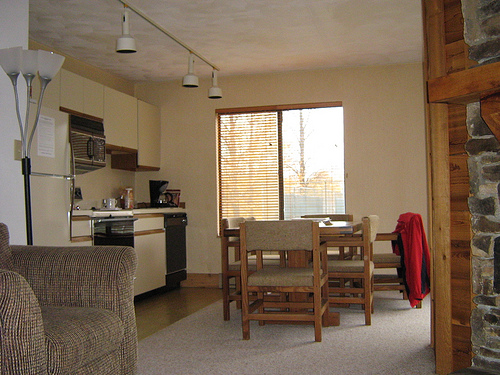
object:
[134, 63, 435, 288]
wall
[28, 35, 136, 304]
wall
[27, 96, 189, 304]
kitchenette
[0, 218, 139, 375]
chair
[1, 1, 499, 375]
room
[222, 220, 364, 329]
table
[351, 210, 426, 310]
chair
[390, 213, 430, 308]
jacket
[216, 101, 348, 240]
window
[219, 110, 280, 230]
blinds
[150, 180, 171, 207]
pot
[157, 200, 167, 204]
coffee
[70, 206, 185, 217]
counter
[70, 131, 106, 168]
microwave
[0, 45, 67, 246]
lamp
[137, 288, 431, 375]
carpet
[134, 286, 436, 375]
floor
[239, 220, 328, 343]
chair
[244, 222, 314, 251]
back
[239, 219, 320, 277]
top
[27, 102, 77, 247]
fridge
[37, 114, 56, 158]
paper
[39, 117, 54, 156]
lettering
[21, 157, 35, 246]
pole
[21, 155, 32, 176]
top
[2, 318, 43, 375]
pattern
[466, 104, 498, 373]
place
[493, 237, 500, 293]
fire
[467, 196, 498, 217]
brick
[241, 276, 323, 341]
bottom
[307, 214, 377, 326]
chairs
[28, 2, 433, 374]
kitchen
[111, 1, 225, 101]
style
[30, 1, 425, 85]
ceiling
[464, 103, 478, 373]
edge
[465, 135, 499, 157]
stone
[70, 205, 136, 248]
stove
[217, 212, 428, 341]
set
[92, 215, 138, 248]
oven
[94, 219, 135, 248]
door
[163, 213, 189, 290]
dishwasher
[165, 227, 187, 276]
metal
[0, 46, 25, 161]
head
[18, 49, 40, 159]
head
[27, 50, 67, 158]
head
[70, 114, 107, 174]
steel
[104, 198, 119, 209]
cup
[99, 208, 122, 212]
plate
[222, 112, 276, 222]
tree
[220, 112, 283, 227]
window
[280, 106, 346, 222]
window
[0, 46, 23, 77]
bulb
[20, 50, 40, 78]
bulb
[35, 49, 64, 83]
bulb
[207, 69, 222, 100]
lights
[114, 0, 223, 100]
row